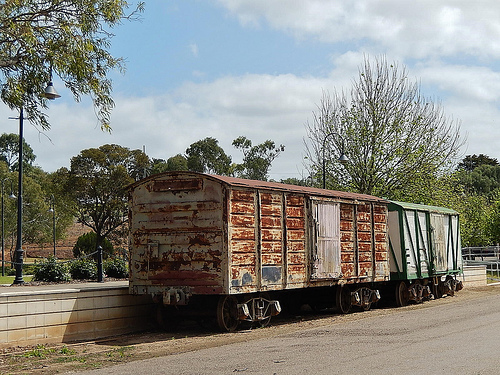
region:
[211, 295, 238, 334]
the wheel of a train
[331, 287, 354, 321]
the wheel of a train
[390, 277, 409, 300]
the wheel of a train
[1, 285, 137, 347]
a wall made of bricks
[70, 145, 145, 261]
a tree in a distance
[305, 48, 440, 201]
a tree in a distance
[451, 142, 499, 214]
a tree in a distance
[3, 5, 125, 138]
a tree in a distance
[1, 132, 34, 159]
a tree in a distance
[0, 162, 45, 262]
a tree in a distance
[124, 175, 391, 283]
A dilapidated red-brown box car from a train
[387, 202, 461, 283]
A restored box car from a train painted white with green trim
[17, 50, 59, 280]
A streetlight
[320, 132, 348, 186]
A streetlight in the background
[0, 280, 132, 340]
A low wall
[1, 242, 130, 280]
A chain marking the boundary of the path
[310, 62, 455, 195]
Top of a tree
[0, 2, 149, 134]
Hanging tree branches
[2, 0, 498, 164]
Partly cloudy sky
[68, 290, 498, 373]
A road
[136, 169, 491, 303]
The train cars are old and rusty.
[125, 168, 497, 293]
Train cars are parked.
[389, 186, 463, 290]
The train car is green and white.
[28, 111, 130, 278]
The trees are green.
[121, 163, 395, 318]
The train car is rusted.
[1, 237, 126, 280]
a chain separates the pole and trees.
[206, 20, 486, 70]
The sky is blue and cloudy.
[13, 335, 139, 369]
The grass is dried up.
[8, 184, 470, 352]
The train cars sits next to a wall.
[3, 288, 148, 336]
The wall is rusted at the bottom.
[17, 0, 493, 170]
A sky with clouds.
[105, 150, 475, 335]
A rusty part of a train.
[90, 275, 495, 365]
A gray road with no litter.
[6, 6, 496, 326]
A sunny day during the daytime.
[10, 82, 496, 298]
A row of green trees.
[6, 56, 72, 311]
A lamppost on the left.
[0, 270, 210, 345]
A white wall with brown dirt.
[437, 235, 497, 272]
A silver fence in the distance.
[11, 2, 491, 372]
A scene outdoors on street.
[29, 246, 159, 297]
Three green bushes near wall.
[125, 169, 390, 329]
rusted train wagon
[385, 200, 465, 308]
white and green train wagon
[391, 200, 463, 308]
white-green train wagon is parked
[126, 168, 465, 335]
two train wagons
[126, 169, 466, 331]
two train wagons are parked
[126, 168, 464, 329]
two forgotten train wagons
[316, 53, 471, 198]
tree with few leaves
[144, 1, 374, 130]
blue sky with few clouds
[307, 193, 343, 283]
white door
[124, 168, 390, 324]
rusty wagon with white door